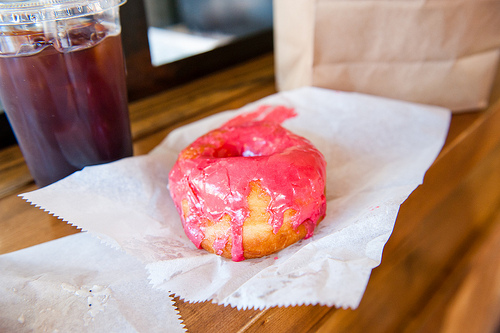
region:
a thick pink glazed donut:
[170, 118, 323, 253]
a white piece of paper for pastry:
[22, 88, 448, 308]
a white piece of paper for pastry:
[3, 228, 185, 330]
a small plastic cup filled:
[1, 3, 133, 183]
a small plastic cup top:
[2, 0, 127, 20]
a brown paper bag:
[272, 0, 499, 110]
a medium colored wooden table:
[0, 23, 499, 332]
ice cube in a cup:
[61, 21, 103, 47]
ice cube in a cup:
[17, 35, 52, 57]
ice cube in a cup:
[42, 18, 83, 33]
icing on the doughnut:
[187, 105, 327, 259]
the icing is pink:
[173, 108, 325, 250]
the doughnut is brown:
[243, 190, 302, 260]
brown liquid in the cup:
[2, 14, 168, 224]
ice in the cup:
[11, 30, 40, 62]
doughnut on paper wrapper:
[151, 82, 380, 305]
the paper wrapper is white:
[189, 72, 448, 314]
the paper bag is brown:
[262, 3, 489, 110]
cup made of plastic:
[0, 1, 180, 192]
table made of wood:
[7, 51, 489, 319]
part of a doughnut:
[228, 116, 276, 178]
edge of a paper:
[280, 269, 313, 304]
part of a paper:
[256, 230, 302, 297]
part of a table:
[218, 302, 233, 320]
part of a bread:
[247, 210, 288, 251]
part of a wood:
[218, 300, 236, 323]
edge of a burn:
[223, 195, 263, 250]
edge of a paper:
[231, 293, 255, 323]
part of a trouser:
[55, 131, 90, 168]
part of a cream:
[264, 203, 284, 228]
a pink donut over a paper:
[168, 103, 336, 276]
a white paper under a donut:
[38, 75, 455, 310]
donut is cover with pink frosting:
[164, 108, 351, 262]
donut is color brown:
[185, 180, 315, 261]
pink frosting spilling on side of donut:
[183, 174, 330, 259]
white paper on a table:
[3, 233, 193, 331]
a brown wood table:
[3, 54, 497, 331]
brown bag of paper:
[264, 0, 499, 113]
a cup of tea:
[0, 4, 149, 195]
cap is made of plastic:
[1, 0, 151, 190]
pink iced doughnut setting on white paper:
[17, 91, 459, 319]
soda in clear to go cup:
[0, 0, 162, 191]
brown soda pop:
[1, 27, 142, 190]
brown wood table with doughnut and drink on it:
[8, 43, 495, 328]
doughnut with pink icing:
[163, 120, 325, 257]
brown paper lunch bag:
[260, 0, 498, 115]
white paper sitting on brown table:
[18, 164, 169, 289]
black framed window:
[115, 0, 289, 104]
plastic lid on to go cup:
[3, 2, 133, 35]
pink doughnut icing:
[185, 126, 312, 196]